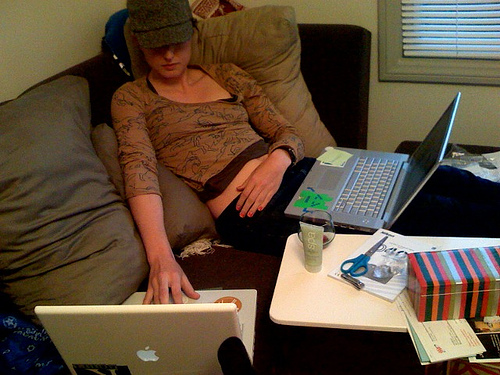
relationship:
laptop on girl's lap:
[279, 91, 469, 239] [207, 145, 498, 271]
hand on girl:
[235, 163, 292, 219] [81, 3, 313, 289]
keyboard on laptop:
[330, 154, 399, 216] [286, 89, 464, 229]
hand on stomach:
[239, 154, 293, 218] [202, 142, 279, 214]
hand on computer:
[144, 261, 214, 316] [37, 281, 257, 369]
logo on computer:
[134, 346, 160, 362] [38, 286, 255, 373]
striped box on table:
[407, 253, 498, 318] [267, 227, 494, 332]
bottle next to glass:
[299, 221, 326, 271] [303, 205, 335, 257]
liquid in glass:
[317, 232, 327, 245] [299, 209, 344, 247]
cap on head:
[124, 0, 192, 50] [127, 4, 197, 84]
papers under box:
[401, 287, 486, 362] [406, 247, 498, 322]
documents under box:
[396, 288, 488, 363] [403, 242, 498, 320]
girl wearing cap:
[107, 0, 499, 305] [128, 0, 197, 47]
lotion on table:
[302, 225, 326, 267] [277, 257, 362, 327]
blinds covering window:
[399, 2, 498, 55] [374, 2, 497, 84]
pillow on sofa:
[120, 2, 335, 161] [2, 4, 370, 374]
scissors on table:
[341, 251, 378, 278] [267, 227, 494, 332]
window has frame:
[400, 1, 498, 58] [373, 1, 497, 82]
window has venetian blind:
[400, 1, 498, 58] [401, 1, 498, 56]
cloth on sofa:
[2, 295, 57, 373] [2, 4, 370, 374]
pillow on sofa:
[0, 74, 148, 323] [2, 4, 370, 374]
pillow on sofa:
[188, 4, 345, 173] [2, 4, 370, 374]